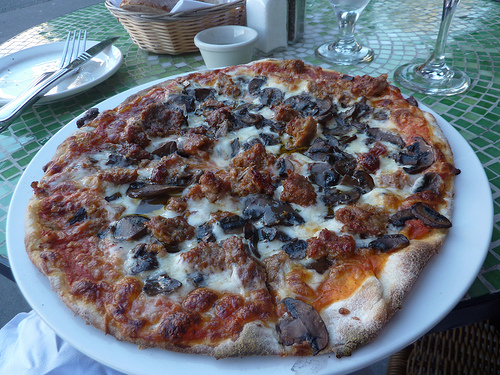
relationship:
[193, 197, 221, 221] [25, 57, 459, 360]
cheese on pizza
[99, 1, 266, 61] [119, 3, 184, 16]
wicker basket of bread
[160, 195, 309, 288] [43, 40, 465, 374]
sauce on pizza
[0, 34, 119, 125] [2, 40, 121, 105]
knife on plate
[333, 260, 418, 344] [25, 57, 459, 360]
crust on pizza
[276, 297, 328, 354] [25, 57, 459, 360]
mushroom on pizza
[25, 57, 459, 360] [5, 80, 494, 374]
pizza on white plate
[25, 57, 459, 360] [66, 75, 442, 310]
pizza topped with mushrooms and cheese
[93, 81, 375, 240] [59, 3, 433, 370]
tomato sauce on pizza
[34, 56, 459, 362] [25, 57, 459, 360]
cheese on pizza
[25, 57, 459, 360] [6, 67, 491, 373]
pizza on dish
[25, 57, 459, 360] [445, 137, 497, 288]
pizza on plate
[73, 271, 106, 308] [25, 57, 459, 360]
cheese on pizza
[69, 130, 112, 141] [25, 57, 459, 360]
cheese on pizza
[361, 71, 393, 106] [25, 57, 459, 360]
cheese on pizza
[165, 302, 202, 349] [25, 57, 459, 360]
cheese on pizza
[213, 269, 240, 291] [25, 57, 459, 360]
cheese on pizza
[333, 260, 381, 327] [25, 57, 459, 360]
crust on pizza